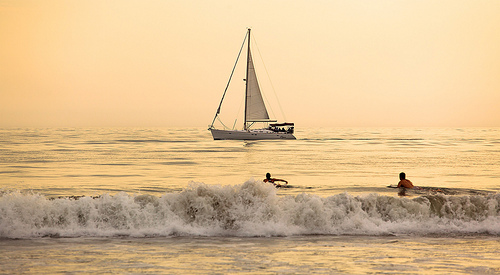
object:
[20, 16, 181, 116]
sky clouds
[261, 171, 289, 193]
people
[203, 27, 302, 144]
sailboat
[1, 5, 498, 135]
sky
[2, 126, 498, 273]
water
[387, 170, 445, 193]
people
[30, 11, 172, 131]
clouds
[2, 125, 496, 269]
ripples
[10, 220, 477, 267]
beach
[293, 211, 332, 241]
badsentence